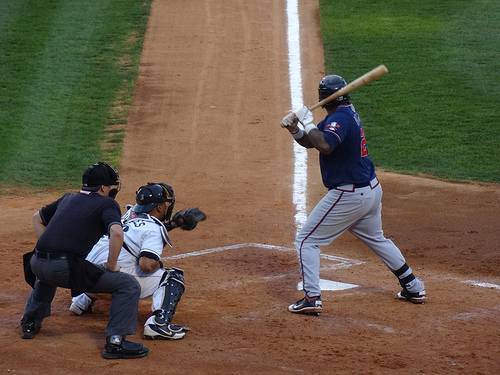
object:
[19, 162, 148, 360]
man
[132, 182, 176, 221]
catchers mask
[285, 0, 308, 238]
line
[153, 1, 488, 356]
dirt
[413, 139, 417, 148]
ground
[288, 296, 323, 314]
clet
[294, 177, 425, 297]
pant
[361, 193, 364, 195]
button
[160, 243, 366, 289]
plate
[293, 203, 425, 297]
legs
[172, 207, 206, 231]
mitt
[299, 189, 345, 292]
stripes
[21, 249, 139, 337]
pants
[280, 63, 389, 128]
bat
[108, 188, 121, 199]
face guard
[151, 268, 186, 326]
protector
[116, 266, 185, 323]
leg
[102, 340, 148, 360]
shoes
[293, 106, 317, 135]
white gloves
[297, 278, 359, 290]
home plate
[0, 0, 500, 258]
baseball field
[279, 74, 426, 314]
batter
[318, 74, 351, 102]
helmet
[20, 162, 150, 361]
umpire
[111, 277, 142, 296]
knee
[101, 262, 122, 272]
hand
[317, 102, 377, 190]
shirt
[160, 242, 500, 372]
batters box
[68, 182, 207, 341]
catcher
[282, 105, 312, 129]
hands